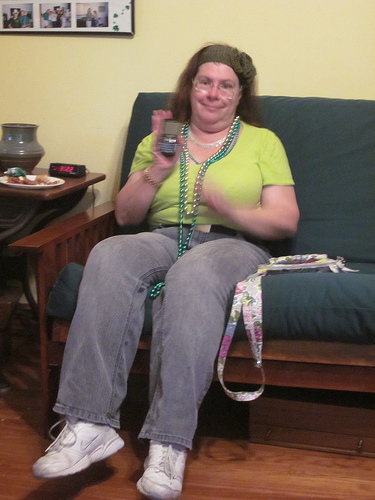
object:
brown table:
[0, 165, 106, 201]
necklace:
[145, 113, 241, 300]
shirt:
[127, 119, 295, 234]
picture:
[1, 2, 39, 27]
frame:
[0, 27, 133, 40]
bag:
[216, 253, 359, 405]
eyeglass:
[189, 78, 245, 101]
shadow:
[33, 420, 125, 479]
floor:
[0, 360, 375, 499]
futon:
[48, 91, 375, 352]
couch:
[10, 92, 374, 460]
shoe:
[135, 439, 186, 498]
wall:
[2, 2, 375, 241]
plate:
[0, 167, 65, 187]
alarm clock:
[49, 162, 87, 178]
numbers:
[55, 164, 72, 172]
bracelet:
[143, 164, 162, 189]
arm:
[6, 199, 116, 254]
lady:
[21, 44, 303, 499]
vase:
[2, 122, 46, 171]